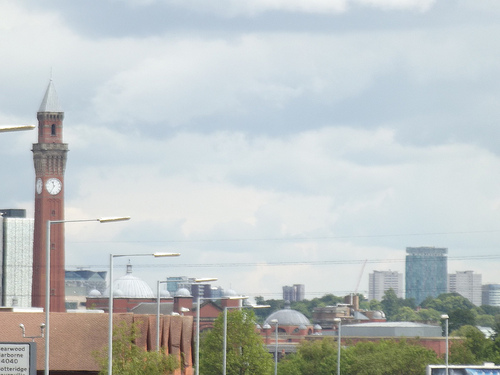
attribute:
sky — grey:
[15, 2, 500, 248]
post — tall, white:
[38, 208, 123, 374]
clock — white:
[43, 177, 62, 197]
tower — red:
[27, 72, 77, 309]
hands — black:
[52, 181, 59, 191]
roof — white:
[107, 254, 151, 297]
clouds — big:
[113, 125, 416, 191]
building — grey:
[253, 298, 314, 327]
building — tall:
[398, 240, 450, 302]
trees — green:
[206, 309, 272, 375]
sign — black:
[1, 336, 33, 374]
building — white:
[0, 208, 35, 310]